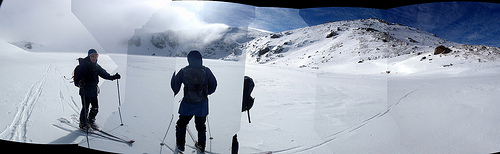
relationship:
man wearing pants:
[73, 47, 120, 132] [81, 94, 99, 127]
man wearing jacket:
[170, 48, 219, 152] [173, 64, 217, 113]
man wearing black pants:
[170, 48, 219, 152] [172, 111, 207, 149]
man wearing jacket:
[170, 48, 219, 152] [163, 66, 220, 118]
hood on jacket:
[186, 50, 204, 64] [163, 66, 220, 118]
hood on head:
[186, 50, 204, 64] [187, 49, 202, 64]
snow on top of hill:
[224, 17, 497, 67] [224, 16, 498, 81]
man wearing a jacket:
[169, 49, 218, 154] [170, 66, 218, 117]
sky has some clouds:
[351, 13, 488, 45] [409, 3, 473, 37]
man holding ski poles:
[72, 48, 121, 133] [71, 71, 128, 134]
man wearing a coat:
[72, 48, 121, 133] [73, 52, 113, 94]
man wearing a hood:
[169, 49, 218, 154] [179, 45, 208, 72]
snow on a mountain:
[319, 80, 406, 142] [99, 16, 499, 66]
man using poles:
[72, 48, 121, 133] [111, 71, 126, 123]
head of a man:
[85, 52, 97, 63] [73, 47, 120, 132]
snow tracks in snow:
[0, 62, 80, 137] [1, 50, 495, 154]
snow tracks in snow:
[251, 86, 418, 152] [1, 50, 495, 154]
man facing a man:
[72, 48, 121, 133] [169, 49, 218, 154]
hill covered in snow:
[259, 14, 494, 78] [316, 79, 499, 148]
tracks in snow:
[3, 68, 78, 154] [4, 52, 61, 138]